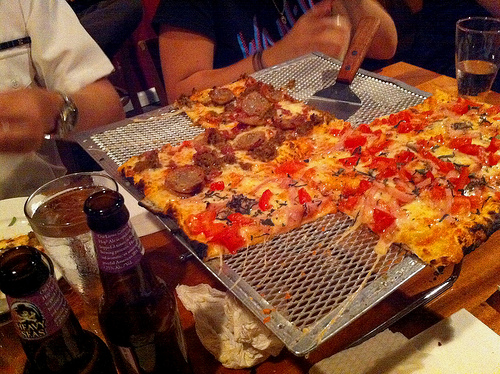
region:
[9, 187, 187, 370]
two bottles of beer with purple labels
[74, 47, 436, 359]
a rectangular metal pizza pan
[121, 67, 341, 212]
three pieces of pizza with meat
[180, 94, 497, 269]
five piece of pizza with veggies and cheese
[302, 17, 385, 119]
a silver spatula with wood handle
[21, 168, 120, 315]
a glass of water by the beer bottles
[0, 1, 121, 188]
the man in the white shirt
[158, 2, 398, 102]
the female in the black shirt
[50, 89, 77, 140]
a wristwatch on the man's wrist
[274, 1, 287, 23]
a gold necklace on the woman.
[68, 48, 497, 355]
A silver metal pizza rack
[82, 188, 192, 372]
A bottle of beer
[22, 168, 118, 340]
A glass of ice water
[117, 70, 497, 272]
A half eaten pizze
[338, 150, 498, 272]
A slice of veggie pizza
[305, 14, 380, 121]
A pizza spatula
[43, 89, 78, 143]
A wrist watch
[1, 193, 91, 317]
A white dinner plate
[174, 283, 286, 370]
A crumpled paper napkin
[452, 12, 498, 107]
A GLASS OF WATER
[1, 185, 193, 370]
TWO BOTTLES OF BEER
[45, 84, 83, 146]
A MANS WATCH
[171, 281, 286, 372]
A DIRTY NAPKIN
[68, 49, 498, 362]
PIZZA ON A METAL TRAY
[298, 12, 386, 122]
A SERVING SPATULA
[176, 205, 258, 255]
TOMATOES ON A PIZZA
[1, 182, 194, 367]
TWO BROWN BOTTLES ON THE TABLE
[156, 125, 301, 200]
SAUSAGE ON A PIZZA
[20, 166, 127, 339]
A GLASS OF ICE WATER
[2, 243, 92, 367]
the top of a beer bottle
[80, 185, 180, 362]
a beer bottle with a purple label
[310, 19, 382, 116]
a spatula is on a pan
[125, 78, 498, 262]
a pizza with different toppings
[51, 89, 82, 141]
a man's wristwatch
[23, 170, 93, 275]
a glass of ice water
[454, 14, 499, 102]
a half filled glass of water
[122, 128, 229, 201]
a slice of pizza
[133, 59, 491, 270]
a pizza on a pan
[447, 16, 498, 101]
glass on table half-filled with beer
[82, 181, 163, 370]
beer bottle with purple label around neck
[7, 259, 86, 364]
logo for Heavy Seas beer on neck of bottle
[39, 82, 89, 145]
man's arm with wrist watch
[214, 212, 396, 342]
aluminum pizza screen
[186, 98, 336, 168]
pizza with pepperoni topping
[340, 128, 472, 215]
cheesy pizza with red pepper topping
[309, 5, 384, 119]
spatula for serving pizza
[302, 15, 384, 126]
wooden handled pizza spatula under slice of pizza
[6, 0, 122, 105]
man's white shirt sleeve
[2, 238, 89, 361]
brown colored beer bottle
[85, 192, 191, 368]
a brown glass bottle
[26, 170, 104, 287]
a glass with water and ice in it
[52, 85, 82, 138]
a person wearing a wrist watch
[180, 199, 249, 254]
sliced tomatoes on a pizza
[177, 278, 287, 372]
a napkin wadded up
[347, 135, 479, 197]
sliced tomatoes on a slices of pizza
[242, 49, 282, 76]
a person wearing wrist bands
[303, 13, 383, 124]
a large brown and gray spatula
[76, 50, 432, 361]
a large gray rack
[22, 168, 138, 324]
a tall glass of water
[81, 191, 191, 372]
a tall brown beer bottle